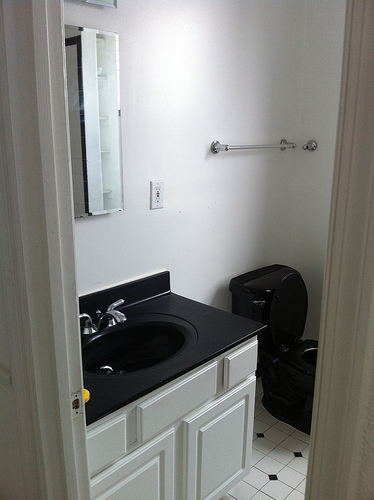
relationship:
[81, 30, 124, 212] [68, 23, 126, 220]
mirror on cabinet